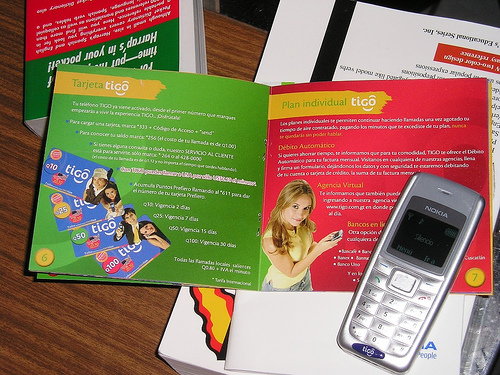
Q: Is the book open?
A: Yes, the book is open.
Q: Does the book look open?
A: Yes, the book is open.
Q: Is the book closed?
A: No, the book is open.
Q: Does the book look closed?
A: No, the book is open.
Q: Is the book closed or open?
A: The book is open.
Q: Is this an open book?
A: Yes, this is an open book.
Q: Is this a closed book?
A: No, this is an open book.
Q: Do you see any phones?
A: Yes, there is a phone.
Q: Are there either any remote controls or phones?
A: Yes, there is a phone.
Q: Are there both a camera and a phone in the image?
A: No, there is a phone but no cameras.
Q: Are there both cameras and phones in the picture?
A: No, there is a phone but no cameras.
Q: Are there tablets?
A: No, there are no tablets.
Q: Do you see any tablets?
A: No, there are no tablets.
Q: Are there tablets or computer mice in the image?
A: No, there are no tablets or computer mice.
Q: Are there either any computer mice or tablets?
A: No, there are no tablets or computer mice.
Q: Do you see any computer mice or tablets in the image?
A: No, there are no tablets or computer mice.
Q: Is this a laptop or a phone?
A: This is a phone.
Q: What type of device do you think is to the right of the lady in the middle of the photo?
A: The device is a phone.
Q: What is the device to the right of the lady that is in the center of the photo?
A: The device is a phone.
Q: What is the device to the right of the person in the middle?
A: The device is a phone.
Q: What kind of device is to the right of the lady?
A: The device is a phone.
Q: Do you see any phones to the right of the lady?
A: Yes, there is a phone to the right of the lady.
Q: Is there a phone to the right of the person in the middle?
A: Yes, there is a phone to the right of the lady.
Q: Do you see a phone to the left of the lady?
A: No, the phone is to the right of the lady.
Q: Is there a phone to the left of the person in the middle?
A: No, the phone is to the right of the lady.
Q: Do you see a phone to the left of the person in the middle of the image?
A: No, the phone is to the right of the lady.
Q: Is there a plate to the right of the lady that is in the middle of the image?
A: No, there is a phone to the right of the lady.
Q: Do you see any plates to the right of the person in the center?
A: No, there is a phone to the right of the lady.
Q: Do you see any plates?
A: No, there are no plates.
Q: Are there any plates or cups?
A: No, there are no plates or cups.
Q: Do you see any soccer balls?
A: No, there are no soccer balls.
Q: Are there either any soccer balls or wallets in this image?
A: No, there are no soccer balls or wallets.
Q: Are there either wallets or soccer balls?
A: No, there are no soccer balls or wallets.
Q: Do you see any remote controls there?
A: No, there are no remote controls.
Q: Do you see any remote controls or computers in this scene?
A: No, there are no remote controls or computers.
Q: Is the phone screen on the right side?
A: Yes, the screen is on the right of the image.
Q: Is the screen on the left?
A: No, the screen is on the right of the image.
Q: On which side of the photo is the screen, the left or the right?
A: The screen is on the right of the image.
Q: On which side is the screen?
A: The screen is on the right of the image.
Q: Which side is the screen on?
A: The screen is on the right of the image.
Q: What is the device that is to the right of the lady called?
A: The device is a screen.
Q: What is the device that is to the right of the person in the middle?
A: The device is a screen.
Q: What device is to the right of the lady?
A: The device is a screen.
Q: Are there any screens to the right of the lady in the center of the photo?
A: Yes, there is a screen to the right of the lady.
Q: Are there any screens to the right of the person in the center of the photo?
A: Yes, there is a screen to the right of the lady.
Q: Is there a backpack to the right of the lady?
A: No, there is a screen to the right of the lady.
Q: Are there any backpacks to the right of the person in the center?
A: No, there is a screen to the right of the lady.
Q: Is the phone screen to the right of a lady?
A: Yes, the screen is to the right of a lady.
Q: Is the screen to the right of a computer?
A: No, the screen is to the right of a lady.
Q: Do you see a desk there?
A: Yes, there is a desk.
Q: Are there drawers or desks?
A: Yes, there is a desk.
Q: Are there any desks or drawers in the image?
A: Yes, there is a desk.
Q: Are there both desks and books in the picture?
A: Yes, there are both a desk and books.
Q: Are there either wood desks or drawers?
A: Yes, there is a wood desk.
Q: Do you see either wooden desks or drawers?
A: Yes, there is a wood desk.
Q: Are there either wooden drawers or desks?
A: Yes, there is a wood desk.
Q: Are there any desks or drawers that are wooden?
A: Yes, the desk is wooden.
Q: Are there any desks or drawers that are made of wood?
A: Yes, the desk is made of wood.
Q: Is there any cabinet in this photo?
A: No, there are no cabinets.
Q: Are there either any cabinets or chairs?
A: No, there are no cabinets or chairs.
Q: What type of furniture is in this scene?
A: The furniture is a desk.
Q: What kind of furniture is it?
A: The piece of furniture is a desk.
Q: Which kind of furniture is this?
A: This is a desk.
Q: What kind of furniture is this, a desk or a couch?
A: This is a desk.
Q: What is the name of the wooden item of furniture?
A: The piece of furniture is a desk.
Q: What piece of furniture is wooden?
A: The piece of furniture is a desk.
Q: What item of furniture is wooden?
A: The piece of furniture is a desk.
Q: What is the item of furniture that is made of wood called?
A: The piece of furniture is a desk.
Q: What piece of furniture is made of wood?
A: The piece of furniture is a desk.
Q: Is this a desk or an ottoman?
A: This is a desk.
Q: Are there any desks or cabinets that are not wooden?
A: No, there is a desk but it is wooden.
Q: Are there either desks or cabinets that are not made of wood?
A: No, there is a desk but it is made of wood.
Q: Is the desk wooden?
A: Yes, the desk is wooden.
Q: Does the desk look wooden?
A: Yes, the desk is wooden.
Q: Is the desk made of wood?
A: Yes, the desk is made of wood.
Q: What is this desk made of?
A: The desk is made of wood.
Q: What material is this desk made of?
A: The desk is made of wood.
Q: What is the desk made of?
A: The desk is made of wood.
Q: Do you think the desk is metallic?
A: No, the desk is wooden.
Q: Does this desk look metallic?
A: No, the desk is wooden.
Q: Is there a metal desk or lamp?
A: No, there is a desk but it is wooden.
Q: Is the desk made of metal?
A: No, the desk is made of wood.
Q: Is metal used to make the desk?
A: No, the desk is made of wood.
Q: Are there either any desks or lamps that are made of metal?
A: No, there is a desk but it is made of wood.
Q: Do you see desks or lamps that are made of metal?
A: No, there is a desk but it is made of wood.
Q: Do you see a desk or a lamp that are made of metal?
A: No, there is a desk but it is made of wood.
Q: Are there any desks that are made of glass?
A: No, there is a desk but it is made of wood.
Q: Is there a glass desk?
A: No, there is a desk but it is made of wood.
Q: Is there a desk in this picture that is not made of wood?
A: No, there is a desk but it is made of wood.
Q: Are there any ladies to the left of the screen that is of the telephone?
A: Yes, there is a lady to the left of the screen.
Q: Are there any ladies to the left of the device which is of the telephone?
A: Yes, there is a lady to the left of the screen.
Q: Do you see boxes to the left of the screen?
A: No, there is a lady to the left of the screen.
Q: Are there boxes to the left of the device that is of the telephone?
A: No, there is a lady to the left of the screen.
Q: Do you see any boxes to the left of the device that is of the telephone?
A: No, there is a lady to the left of the screen.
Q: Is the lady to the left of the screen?
A: Yes, the lady is to the left of the screen.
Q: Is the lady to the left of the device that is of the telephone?
A: Yes, the lady is to the left of the screen.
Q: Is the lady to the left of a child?
A: No, the lady is to the left of the screen.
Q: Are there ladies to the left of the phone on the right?
A: Yes, there is a lady to the left of the telephone.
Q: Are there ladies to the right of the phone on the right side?
A: No, the lady is to the left of the telephone.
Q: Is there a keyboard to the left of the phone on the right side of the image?
A: No, there is a lady to the left of the telephone.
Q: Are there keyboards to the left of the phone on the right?
A: No, there is a lady to the left of the telephone.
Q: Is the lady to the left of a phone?
A: Yes, the lady is to the left of a phone.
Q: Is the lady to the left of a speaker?
A: No, the lady is to the left of a phone.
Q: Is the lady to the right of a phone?
A: No, the lady is to the left of a phone.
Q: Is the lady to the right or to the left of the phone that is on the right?
A: The lady is to the left of the phone.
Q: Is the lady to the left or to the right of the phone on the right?
A: The lady is to the left of the phone.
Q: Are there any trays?
A: No, there are no trays.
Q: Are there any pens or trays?
A: No, there are no trays or pens.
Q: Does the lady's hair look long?
A: Yes, the hair is long.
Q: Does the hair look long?
A: Yes, the hair is long.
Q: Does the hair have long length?
A: Yes, the hair is long.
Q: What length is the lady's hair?
A: The hair is long.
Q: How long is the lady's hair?
A: The hair is long.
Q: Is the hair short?
A: No, the hair is long.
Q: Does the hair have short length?
A: No, the hair is long.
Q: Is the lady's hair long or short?
A: The hair is long.